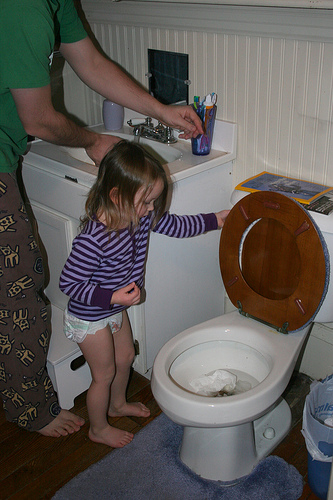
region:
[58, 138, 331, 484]
young child flushing toilet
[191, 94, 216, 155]
purple glass with toothbrushes and toothpaste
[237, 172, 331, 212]
magazines on the toilet tank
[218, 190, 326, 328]
a brown raised up toilet seat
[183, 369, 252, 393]
white toilet paper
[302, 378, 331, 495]
partial view of a blue wastebasket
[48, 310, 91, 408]
small white step stool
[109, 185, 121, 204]
little girl's right ear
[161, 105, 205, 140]
a grownups hand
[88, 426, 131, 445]
a little girl's right foot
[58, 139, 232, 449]
a small girl next to the toilet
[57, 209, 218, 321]
purple striped shirt on girl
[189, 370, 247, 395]
waste in toilet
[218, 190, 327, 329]
a wooden toilet seat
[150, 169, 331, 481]
a white toilet in the bathroom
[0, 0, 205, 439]
a man standing next to the girl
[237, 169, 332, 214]
magazines on top of the toilet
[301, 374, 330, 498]
blue garbage can next to toilet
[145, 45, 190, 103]
small mirror above sink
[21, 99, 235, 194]
white sink in the bathroom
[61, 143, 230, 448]
a little girl in a diaper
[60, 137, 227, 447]
a little girl flushing the toilet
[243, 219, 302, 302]
a wooden lid for a toilet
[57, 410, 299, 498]
a blue toilet bowl rug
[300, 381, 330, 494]
a small blue trash can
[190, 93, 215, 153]
a cup with toothpaste and brushes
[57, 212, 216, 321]
a long sleeve purple striped shirt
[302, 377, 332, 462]
a white plastic trash bag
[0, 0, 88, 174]
a green short sleeve shirt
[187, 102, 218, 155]
a blue glass on a counter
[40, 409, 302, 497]
a blue rug on the bathroom floor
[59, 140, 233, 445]
a little girl flushing a toilet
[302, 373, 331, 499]
a blue wastebasket with a plastic bag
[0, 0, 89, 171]
man wearing a green shirt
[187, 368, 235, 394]
toilet paper in a toilet bowl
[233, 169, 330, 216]
magazines on top of a toilet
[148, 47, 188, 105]
a small mirror on a wall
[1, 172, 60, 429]
a man wearing pajama bottoms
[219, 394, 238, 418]
edge of a toilet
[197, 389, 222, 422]
part of a toilet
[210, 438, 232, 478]
part of a toilet